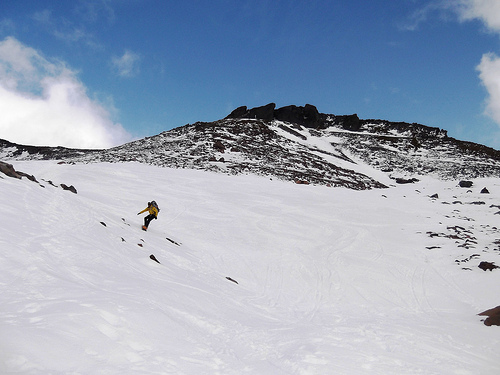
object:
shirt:
[139, 206, 161, 218]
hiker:
[137, 201, 160, 231]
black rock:
[165, 237, 184, 248]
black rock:
[121, 216, 128, 223]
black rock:
[148, 254, 162, 265]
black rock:
[99, 221, 107, 227]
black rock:
[137, 242, 144, 249]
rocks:
[424, 244, 441, 250]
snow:
[6, 161, 496, 375]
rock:
[1, 156, 21, 179]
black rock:
[226, 277, 240, 283]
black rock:
[46, 179, 60, 189]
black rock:
[38, 184, 48, 191]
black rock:
[58, 182, 80, 195]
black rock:
[120, 237, 127, 241]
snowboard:
[141, 225, 148, 231]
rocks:
[248, 102, 276, 114]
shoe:
[142, 225, 148, 230]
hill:
[0, 101, 497, 375]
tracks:
[162, 274, 226, 299]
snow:
[257, 244, 429, 331]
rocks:
[224, 104, 247, 119]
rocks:
[476, 260, 499, 271]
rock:
[56, 160, 65, 165]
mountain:
[0, 99, 497, 182]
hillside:
[0, 161, 499, 372]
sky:
[0, 0, 498, 152]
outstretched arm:
[137, 206, 148, 215]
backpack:
[151, 200, 160, 210]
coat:
[139, 205, 159, 217]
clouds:
[111, 46, 145, 83]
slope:
[1, 122, 497, 373]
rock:
[218, 156, 226, 162]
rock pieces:
[444, 215, 451, 218]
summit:
[105, 99, 498, 153]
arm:
[153, 209, 159, 220]